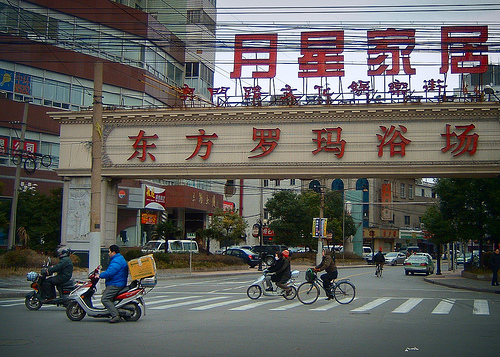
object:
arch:
[330, 176, 346, 186]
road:
[163, 293, 493, 320]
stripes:
[351, 296, 392, 312]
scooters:
[25, 257, 76, 310]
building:
[0, 5, 183, 242]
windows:
[15, 72, 32, 95]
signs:
[144, 185, 166, 211]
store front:
[139, 181, 174, 237]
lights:
[312, 186, 320, 193]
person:
[493, 249, 500, 287]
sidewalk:
[460, 275, 500, 288]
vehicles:
[403, 251, 434, 276]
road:
[358, 259, 439, 278]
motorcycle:
[68, 263, 162, 325]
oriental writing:
[228, 25, 490, 81]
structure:
[224, 22, 492, 83]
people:
[313, 248, 339, 302]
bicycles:
[294, 266, 357, 305]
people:
[41, 246, 77, 301]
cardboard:
[128, 253, 157, 281]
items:
[141, 275, 156, 288]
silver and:
[64, 266, 160, 326]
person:
[262, 251, 284, 291]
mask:
[274, 254, 279, 260]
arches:
[356, 178, 369, 187]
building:
[211, 176, 444, 250]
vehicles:
[141, 239, 200, 254]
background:
[143, 236, 259, 271]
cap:
[58, 246, 71, 257]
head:
[56, 244, 71, 258]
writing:
[121, 125, 486, 162]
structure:
[46, 106, 500, 178]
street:
[0, 224, 480, 323]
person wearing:
[277, 248, 291, 294]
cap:
[281, 250, 289, 258]